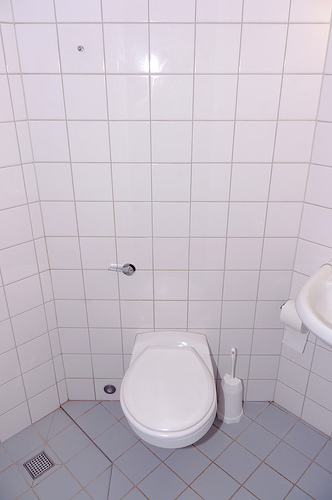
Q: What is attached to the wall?
A: The toilet.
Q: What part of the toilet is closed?
A: The lid.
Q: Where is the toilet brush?
A: To the right of the toilet.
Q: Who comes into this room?
A: People who have to urinate.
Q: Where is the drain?
A: To the left of the toilet.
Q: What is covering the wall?
A: White tile.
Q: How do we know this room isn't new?
A: Floor grout is dirty.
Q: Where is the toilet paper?
A: Between the sink and toilet.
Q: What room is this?
A: Bathroom.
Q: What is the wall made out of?
A: Tile.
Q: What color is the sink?
A: White.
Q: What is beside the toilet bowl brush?
A: The toilet.